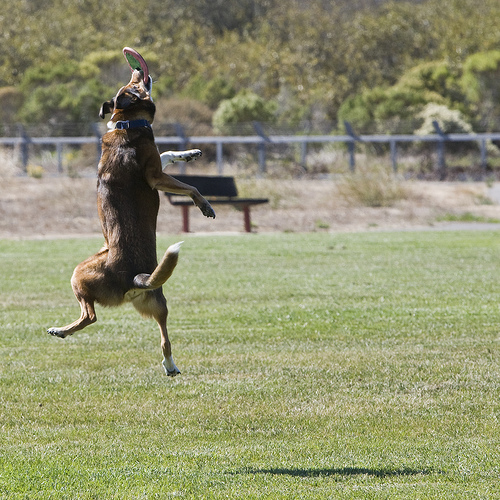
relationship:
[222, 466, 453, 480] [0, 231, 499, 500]
shadow showing on grass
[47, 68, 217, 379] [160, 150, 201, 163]
dog has front leg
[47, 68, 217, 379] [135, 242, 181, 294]
dog has tail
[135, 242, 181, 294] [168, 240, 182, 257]
tail has white tip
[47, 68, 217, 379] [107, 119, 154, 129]
dog has collar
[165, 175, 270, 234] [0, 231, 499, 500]
bench near grass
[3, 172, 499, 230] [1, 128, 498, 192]
grass under fence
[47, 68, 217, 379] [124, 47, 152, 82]
dog catches frisbee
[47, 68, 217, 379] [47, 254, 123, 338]
dog has hind leg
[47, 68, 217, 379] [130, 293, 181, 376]
dog has hind leg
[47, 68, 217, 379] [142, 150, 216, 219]
dog has front leg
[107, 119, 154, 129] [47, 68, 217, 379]
collar around dog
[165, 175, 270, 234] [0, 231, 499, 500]
bench in grass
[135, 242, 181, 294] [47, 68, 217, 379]
tail on dog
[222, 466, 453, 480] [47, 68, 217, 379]
shadow cast by dog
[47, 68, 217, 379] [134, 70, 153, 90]
dog has mouth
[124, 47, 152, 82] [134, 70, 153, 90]
frisbee inside of mouth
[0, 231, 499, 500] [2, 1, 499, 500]
grass inside park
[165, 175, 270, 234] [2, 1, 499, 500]
bench in park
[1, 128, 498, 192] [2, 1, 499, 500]
fence around park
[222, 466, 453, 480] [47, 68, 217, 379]
shadow of dog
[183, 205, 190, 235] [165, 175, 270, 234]
post supports bench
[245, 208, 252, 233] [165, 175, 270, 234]
post supports bench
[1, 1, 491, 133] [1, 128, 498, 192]
trees behind fence